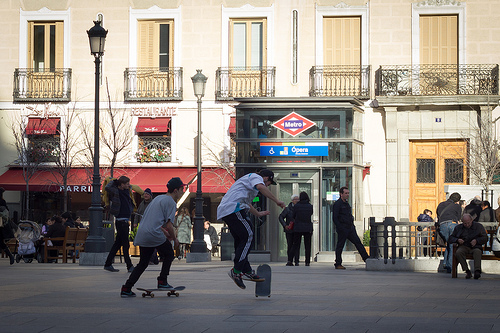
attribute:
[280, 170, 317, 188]
door — large and wooden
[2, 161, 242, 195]
awning — red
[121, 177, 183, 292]
man —  young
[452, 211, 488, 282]
man — sitting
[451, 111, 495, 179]
tree — bare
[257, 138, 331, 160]
sign — handicapped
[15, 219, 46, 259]
carriage — baby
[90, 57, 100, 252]
pole — black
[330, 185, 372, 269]
man — standing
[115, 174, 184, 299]
man — standing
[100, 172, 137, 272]
man — standing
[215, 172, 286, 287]
man — standing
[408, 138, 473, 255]
doors — wood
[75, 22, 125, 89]
lampost — unlit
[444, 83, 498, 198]
tree — leafless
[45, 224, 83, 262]
bench — wooden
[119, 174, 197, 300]
boy — teen, spunky, spirited